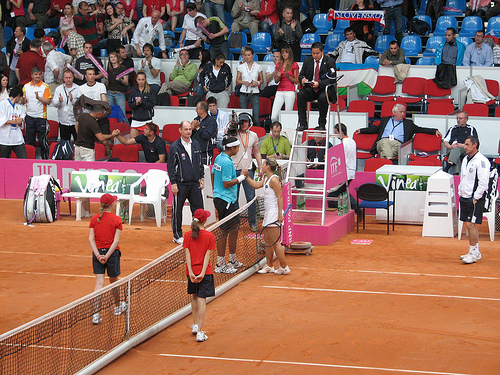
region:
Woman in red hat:
[175, 210, 230, 345]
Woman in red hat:
[80, 192, 131, 347]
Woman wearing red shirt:
[180, 207, 246, 368]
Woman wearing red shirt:
[85, 188, 145, 328]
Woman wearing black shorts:
[180, 205, 217, 336]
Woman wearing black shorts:
[77, 196, 134, 328]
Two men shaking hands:
[71, 99, 161, 173]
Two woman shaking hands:
[209, 133, 296, 280]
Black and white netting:
[32, 287, 182, 373]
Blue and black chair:
[348, 168, 415, 240]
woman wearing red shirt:
[184, 211, 214, 343]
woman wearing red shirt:
[89, 195, 129, 318]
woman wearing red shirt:
[272, 48, 296, 113]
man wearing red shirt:
[17, 40, 47, 80]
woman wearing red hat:
[185, 206, 211, 341]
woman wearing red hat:
[89, 194, 131, 319]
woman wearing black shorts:
[180, 208, 215, 346]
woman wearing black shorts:
[90, 198, 130, 324]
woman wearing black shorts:
[213, 135, 247, 275]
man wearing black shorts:
[457, 137, 487, 266]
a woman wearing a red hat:
[176, 202, 218, 249]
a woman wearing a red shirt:
[175, 204, 217, 303]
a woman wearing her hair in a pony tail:
[175, 197, 218, 257]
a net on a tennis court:
[61, 273, 278, 374]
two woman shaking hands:
[208, 139, 280, 194]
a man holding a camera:
[223, 109, 258, 141]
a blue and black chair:
[349, 181, 397, 237]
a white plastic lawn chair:
[128, 167, 170, 224]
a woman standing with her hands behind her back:
[83, 189, 125, 274]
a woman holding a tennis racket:
[256, 153, 298, 254]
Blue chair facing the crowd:
[351, 180, 396, 235]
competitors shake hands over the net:
[212, 135, 293, 280]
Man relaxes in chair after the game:
[355, 100, 443, 163]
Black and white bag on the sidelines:
[22, 171, 63, 223]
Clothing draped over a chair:
[460, 69, 499, 116]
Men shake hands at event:
[70, 102, 167, 161]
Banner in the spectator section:
[327, 9, 387, 26]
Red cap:
[97, 191, 119, 209]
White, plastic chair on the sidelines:
[127, 163, 171, 226]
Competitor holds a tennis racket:
[245, 158, 294, 275]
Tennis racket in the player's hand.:
[251, 215, 293, 247]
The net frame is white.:
[21, 188, 276, 373]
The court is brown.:
[266, 285, 497, 358]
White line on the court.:
[269, 278, 499, 320]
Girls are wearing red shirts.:
[71, 189, 217, 279]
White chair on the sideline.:
[132, 169, 168, 224]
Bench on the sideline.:
[62, 175, 138, 212]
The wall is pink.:
[6, 157, 177, 204]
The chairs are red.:
[385, 79, 491, 117]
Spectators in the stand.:
[7, 0, 498, 177]